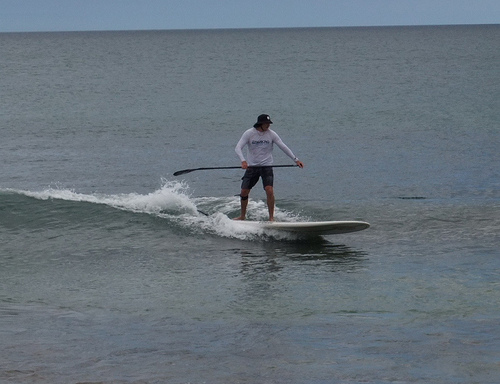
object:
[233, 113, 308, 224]
person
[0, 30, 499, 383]
water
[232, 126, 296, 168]
shirt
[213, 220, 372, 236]
paddleboard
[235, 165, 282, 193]
shorts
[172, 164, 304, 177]
oar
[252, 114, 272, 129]
hat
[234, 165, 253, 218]
leg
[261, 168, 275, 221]
leg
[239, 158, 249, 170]
hand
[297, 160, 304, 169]
hand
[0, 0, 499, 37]
sky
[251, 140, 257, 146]
word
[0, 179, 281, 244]
wave